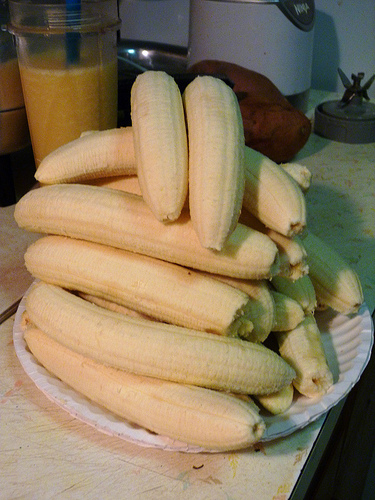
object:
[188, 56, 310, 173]
potato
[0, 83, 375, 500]
counter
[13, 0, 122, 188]
glass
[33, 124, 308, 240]
banana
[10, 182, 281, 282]
banana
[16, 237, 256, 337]
banana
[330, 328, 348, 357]
paper plate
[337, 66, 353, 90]
blades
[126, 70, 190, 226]
banana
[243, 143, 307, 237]
banana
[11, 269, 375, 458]
paper plates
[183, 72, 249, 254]
banana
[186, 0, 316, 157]
base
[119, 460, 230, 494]
scratch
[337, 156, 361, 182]
pattern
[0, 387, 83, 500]
cut marks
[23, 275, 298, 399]
banana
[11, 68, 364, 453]
peeled banana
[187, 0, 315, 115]
blender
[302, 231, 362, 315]
banana